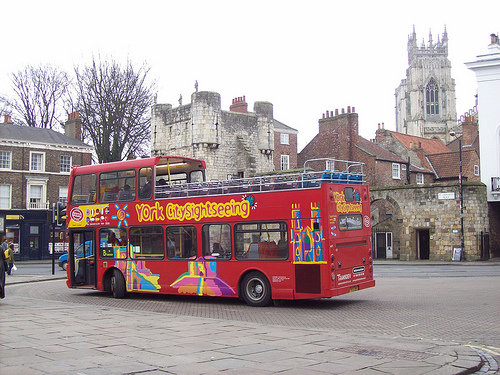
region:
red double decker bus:
[48, 139, 386, 315]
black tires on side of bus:
[99, 263, 276, 310]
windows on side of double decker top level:
[70, 168, 157, 205]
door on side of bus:
[66, 225, 98, 287]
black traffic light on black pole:
[49, 196, 65, 276]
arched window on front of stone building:
[417, 70, 446, 123]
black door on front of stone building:
[405, 220, 439, 262]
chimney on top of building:
[223, 90, 252, 115]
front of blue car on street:
[55, 251, 65, 274]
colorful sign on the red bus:
[68, 192, 278, 226]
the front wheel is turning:
[104, 267, 131, 300]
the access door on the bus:
[70, 223, 100, 296]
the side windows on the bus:
[96, 220, 295, 260]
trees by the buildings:
[8, 48, 153, 165]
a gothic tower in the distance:
[386, 24, 462, 147]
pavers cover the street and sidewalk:
[8, 259, 495, 374]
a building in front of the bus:
[3, 110, 95, 271]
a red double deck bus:
[65, 153, 379, 305]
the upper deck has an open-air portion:
[145, 144, 367, 200]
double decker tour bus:
[62, 158, 379, 308]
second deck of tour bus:
[67, 153, 369, 208]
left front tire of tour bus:
[104, 268, 125, 296]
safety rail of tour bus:
[157, 155, 369, 200]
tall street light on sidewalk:
[443, 127, 467, 267]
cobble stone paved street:
[54, 263, 499, 346]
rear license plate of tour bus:
[346, 282, 361, 295]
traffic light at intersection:
[50, 198, 69, 277]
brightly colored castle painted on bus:
[285, 198, 327, 264]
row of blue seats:
[314, 166, 365, 181]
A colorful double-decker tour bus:
[67, 154, 375, 301]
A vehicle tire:
[235, 273, 275, 306]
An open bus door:
[66, 228, 97, 285]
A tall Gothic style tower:
[385, 33, 461, 129]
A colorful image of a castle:
[285, 206, 325, 265]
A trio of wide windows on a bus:
[67, 171, 159, 201]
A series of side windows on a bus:
[99, 227, 291, 263]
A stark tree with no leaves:
[89, 65, 144, 152]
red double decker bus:
[65, 156, 377, 307]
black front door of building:
[2, 209, 49, 259]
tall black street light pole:
[449, 130, 465, 262]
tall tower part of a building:
[394, 27, 461, 142]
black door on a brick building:
[415, 227, 429, 259]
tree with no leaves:
[54, 50, 152, 169]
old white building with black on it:
[151, 93, 274, 181]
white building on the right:
[462, 42, 499, 199]